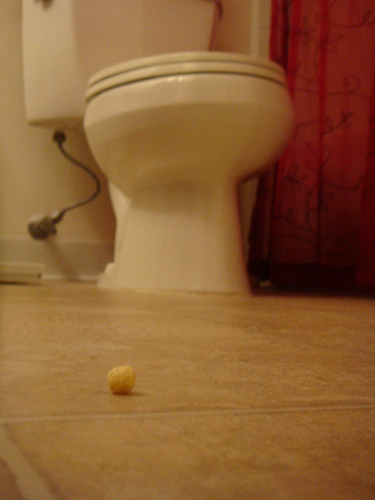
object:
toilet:
[21, 0, 296, 294]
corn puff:
[106, 364, 137, 392]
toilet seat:
[80, 50, 295, 297]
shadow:
[124, 390, 144, 396]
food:
[105, 365, 136, 394]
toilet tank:
[19, 0, 226, 128]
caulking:
[104, 273, 286, 327]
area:
[0, 254, 372, 494]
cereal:
[108, 364, 136, 393]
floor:
[2, 283, 374, 498]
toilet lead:
[126, 42, 291, 76]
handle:
[39, 0, 52, 11]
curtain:
[247, 6, 374, 292]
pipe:
[27, 130, 103, 240]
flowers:
[273, 143, 370, 275]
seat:
[84, 52, 291, 105]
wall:
[0, 0, 256, 287]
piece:
[110, 370, 126, 390]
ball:
[107, 363, 135, 394]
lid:
[85, 51, 286, 103]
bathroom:
[1, 1, 373, 498]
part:
[188, 332, 271, 384]